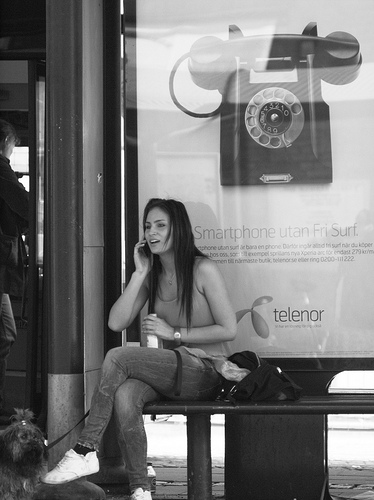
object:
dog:
[0, 407, 50, 499]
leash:
[44, 348, 182, 449]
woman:
[43, 198, 237, 499]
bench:
[142, 392, 373, 499]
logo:
[233, 291, 273, 342]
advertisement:
[120, 1, 373, 359]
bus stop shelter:
[0, 0, 373, 499]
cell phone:
[140, 237, 150, 260]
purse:
[217, 351, 303, 404]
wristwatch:
[172, 325, 181, 347]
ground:
[0, 415, 373, 499]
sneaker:
[40, 445, 100, 485]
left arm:
[174, 256, 237, 341]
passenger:
[1, 120, 30, 418]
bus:
[1, 0, 136, 497]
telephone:
[168, 21, 362, 186]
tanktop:
[151, 257, 226, 358]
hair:
[142, 198, 211, 335]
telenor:
[272, 306, 324, 322]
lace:
[55, 452, 73, 472]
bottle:
[146, 461, 159, 493]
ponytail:
[9, 406, 36, 426]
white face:
[173, 327, 181, 348]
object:
[146, 312, 159, 350]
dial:
[244, 87, 303, 152]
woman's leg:
[43, 346, 214, 448]